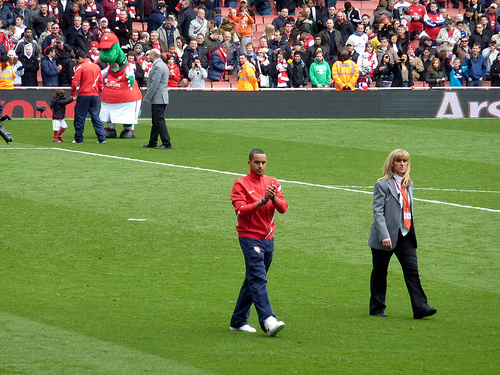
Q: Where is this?
A: This is at the field.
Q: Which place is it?
A: It is a field.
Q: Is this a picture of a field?
A: Yes, it is showing a field.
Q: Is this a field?
A: Yes, it is a field.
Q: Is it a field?
A: Yes, it is a field.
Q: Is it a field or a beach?
A: It is a field.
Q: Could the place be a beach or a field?
A: It is a field.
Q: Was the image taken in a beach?
A: No, the picture was taken in a field.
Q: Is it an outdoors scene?
A: Yes, it is outdoors.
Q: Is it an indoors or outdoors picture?
A: It is outdoors.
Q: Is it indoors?
A: No, it is outdoors.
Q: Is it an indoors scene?
A: No, it is outdoors.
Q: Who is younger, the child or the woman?
A: The child is younger than the woman.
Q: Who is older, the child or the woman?
A: The woman is older than the child.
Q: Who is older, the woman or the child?
A: The woman is older than the child.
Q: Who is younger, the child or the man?
A: The child is younger than the man.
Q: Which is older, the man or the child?
A: The man is older than the child.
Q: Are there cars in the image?
A: No, there are no cars.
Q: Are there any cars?
A: No, there are no cars.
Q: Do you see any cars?
A: No, there are no cars.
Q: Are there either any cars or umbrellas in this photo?
A: No, there are no cars or umbrellas.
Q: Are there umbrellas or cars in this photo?
A: No, there are no cars or umbrellas.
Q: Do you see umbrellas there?
A: No, there are no umbrellas.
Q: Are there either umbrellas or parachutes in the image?
A: No, there are no umbrellas or parachutes.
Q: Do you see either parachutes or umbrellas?
A: No, there are no umbrellas or parachutes.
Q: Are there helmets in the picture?
A: No, there are no helmets.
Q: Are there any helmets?
A: No, there are no helmets.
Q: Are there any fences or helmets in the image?
A: No, there are no helmets or fences.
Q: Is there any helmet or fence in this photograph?
A: No, there are no fences or helmets.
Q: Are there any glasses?
A: No, there are no glasses.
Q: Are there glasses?
A: No, there are no glasses.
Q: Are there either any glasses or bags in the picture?
A: No, there are no glasses or bags.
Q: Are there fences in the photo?
A: No, there are no fences.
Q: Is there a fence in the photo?
A: No, there are no fences.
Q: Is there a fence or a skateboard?
A: No, there are no fences or skateboards.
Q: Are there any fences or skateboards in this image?
A: No, there are no fences or skateboards.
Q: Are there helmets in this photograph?
A: No, there are no helmets.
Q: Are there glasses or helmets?
A: No, there are no helmets or glasses.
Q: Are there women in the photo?
A: Yes, there is a woman.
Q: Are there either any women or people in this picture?
A: Yes, there is a woman.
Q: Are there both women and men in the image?
A: Yes, there are both a woman and a man.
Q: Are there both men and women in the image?
A: Yes, there are both a woman and a man.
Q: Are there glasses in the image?
A: No, there are no glasses.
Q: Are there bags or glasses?
A: No, there are no glasses or bags.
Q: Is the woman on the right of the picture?
A: Yes, the woman is on the right of the image.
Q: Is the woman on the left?
A: No, the woman is on the right of the image.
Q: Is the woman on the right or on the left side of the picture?
A: The woman is on the right of the image.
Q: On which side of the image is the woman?
A: The woman is on the right of the image.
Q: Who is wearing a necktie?
A: The woman is wearing a necktie.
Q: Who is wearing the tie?
A: The woman is wearing a necktie.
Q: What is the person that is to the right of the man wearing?
A: The woman is wearing a tie.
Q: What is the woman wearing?
A: The woman is wearing a tie.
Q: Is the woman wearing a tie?
A: Yes, the woman is wearing a tie.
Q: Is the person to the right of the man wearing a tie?
A: Yes, the woman is wearing a tie.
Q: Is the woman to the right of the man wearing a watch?
A: No, the woman is wearing a tie.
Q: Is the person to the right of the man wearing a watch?
A: No, the woman is wearing a tie.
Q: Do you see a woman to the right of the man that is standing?
A: Yes, there is a woman to the right of the man.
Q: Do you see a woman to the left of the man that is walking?
A: No, the woman is to the right of the man.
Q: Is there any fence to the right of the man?
A: No, there is a woman to the right of the man.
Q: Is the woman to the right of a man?
A: Yes, the woman is to the right of a man.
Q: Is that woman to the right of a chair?
A: No, the woman is to the right of a man.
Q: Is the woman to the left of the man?
A: No, the woman is to the right of the man.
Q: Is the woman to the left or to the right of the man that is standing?
A: The woman is to the right of the man.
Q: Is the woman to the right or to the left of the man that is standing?
A: The woman is to the right of the man.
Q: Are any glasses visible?
A: No, there are no glasses.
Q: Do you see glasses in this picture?
A: No, there are no glasses.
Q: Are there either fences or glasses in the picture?
A: No, there are no glasses or fences.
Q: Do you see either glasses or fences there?
A: No, there are no glasses or fences.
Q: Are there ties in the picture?
A: Yes, there is a tie.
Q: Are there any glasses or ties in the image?
A: Yes, there is a tie.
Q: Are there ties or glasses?
A: Yes, there is a tie.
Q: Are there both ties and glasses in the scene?
A: No, there is a tie but no glasses.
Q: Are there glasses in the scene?
A: No, there are no glasses.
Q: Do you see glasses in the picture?
A: No, there are no glasses.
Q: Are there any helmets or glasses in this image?
A: No, there are no glasses or helmets.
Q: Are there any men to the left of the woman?
A: Yes, there is a man to the left of the woman.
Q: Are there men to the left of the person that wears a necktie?
A: Yes, there is a man to the left of the woman.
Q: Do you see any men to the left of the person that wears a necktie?
A: Yes, there is a man to the left of the woman.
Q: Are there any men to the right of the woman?
A: No, the man is to the left of the woman.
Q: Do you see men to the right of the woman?
A: No, the man is to the left of the woman.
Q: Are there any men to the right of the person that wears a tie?
A: No, the man is to the left of the woman.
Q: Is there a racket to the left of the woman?
A: No, there is a man to the left of the woman.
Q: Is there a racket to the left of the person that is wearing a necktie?
A: No, there is a man to the left of the woman.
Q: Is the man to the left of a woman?
A: Yes, the man is to the left of a woman.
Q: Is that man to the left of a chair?
A: No, the man is to the left of a woman.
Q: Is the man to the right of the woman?
A: No, the man is to the left of the woman.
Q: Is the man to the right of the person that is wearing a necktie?
A: No, the man is to the left of the woman.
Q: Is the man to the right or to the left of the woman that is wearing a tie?
A: The man is to the left of the woman.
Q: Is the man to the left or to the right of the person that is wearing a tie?
A: The man is to the left of the woman.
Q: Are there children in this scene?
A: Yes, there is a child.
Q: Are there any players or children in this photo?
A: Yes, there is a child.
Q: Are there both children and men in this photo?
A: Yes, there are both a child and a man.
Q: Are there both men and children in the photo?
A: Yes, there are both a child and a man.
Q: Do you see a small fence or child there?
A: Yes, there is a small child.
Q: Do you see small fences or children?
A: Yes, there is a small child.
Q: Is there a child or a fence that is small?
A: Yes, the child is small.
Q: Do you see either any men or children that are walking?
A: Yes, the child is walking.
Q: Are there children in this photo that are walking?
A: Yes, there is a child that is walking.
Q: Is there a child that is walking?
A: Yes, there is a child that is walking.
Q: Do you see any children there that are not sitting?
A: Yes, there is a child that is walking .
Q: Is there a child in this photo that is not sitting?
A: Yes, there is a child that is walking.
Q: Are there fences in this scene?
A: No, there are no fences.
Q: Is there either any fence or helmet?
A: No, there are no fences or helmets.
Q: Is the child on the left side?
A: Yes, the child is on the left of the image.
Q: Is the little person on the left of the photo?
A: Yes, the child is on the left of the image.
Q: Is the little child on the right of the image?
A: No, the kid is on the left of the image.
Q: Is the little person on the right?
A: No, the kid is on the left of the image.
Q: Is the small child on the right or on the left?
A: The kid is on the left of the image.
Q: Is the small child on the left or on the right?
A: The kid is on the left of the image.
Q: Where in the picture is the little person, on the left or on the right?
A: The kid is on the left of the image.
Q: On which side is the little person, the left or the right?
A: The kid is on the left of the image.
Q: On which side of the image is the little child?
A: The child is on the left of the image.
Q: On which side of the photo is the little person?
A: The child is on the left of the image.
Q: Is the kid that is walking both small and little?
A: Yes, the child is small and little.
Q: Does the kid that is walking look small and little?
A: Yes, the child is small and little.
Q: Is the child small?
A: Yes, the child is small.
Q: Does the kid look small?
A: Yes, the kid is small.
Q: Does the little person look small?
A: Yes, the kid is small.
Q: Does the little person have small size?
A: Yes, the kid is small.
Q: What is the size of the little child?
A: The kid is small.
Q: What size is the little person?
A: The kid is small.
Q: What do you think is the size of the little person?
A: The kid is small.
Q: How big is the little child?
A: The kid is small.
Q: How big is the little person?
A: The kid is small.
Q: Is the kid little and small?
A: Yes, the kid is little and small.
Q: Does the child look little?
A: Yes, the child is little.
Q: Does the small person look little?
A: Yes, the child is little.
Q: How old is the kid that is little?
A: The child is little.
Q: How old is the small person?
A: The child is little.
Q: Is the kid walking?
A: Yes, the kid is walking.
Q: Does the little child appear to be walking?
A: Yes, the kid is walking.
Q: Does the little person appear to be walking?
A: Yes, the kid is walking.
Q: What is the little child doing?
A: The kid is walking.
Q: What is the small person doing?
A: The kid is walking.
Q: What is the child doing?
A: The kid is walking.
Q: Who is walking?
A: The child is walking.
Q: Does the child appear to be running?
A: No, the child is walking.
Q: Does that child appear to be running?
A: No, the child is walking.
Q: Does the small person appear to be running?
A: No, the child is walking.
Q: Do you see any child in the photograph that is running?
A: No, there is a child but he is walking.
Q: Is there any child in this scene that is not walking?
A: No, there is a child but he is walking.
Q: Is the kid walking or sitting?
A: The kid is walking.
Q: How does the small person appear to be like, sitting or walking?
A: The kid is walking.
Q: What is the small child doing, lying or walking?
A: The child is walking.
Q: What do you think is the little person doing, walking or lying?
A: The child is walking.